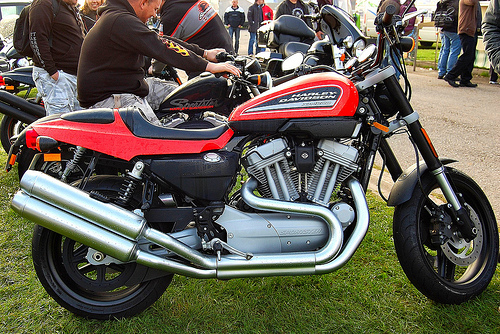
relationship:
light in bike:
[35, 134, 59, 153] [2, 19, 499, 324]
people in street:
[388, 1, 483, 78] [398, 72, 490, 151]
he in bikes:
[73, 0, 236, 124] [44, 10, 491, 320]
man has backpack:
[2, 4, 89, 113] [12, 7, 31, 69]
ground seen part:
[3, 45, 498, 332] [355, 264, 375, 293]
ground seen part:
[3, 45, 498, 332] [335, 272, 358, 312]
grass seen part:
[1, 80, 498, 330] [359, 244, 379, 278]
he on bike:
[73, 4, 236, 124] [0, 50, 306, 177]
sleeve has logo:
[146, 34, 207, 68] [151, 33, 191, 60]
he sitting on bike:
[73, 0, 236, 124] [2, 19, 499, 324]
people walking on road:
[481, 0, 498, 78] [368, 61, 484, 191]